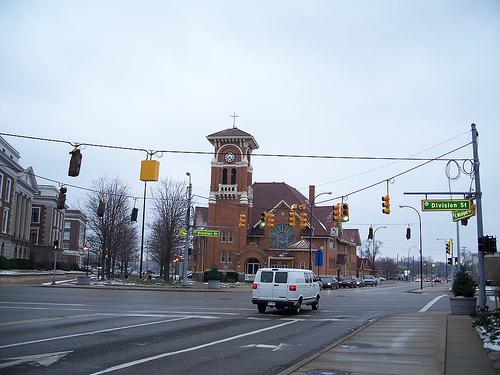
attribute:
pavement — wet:
[123, 309, 180, 359]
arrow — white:
[238, 341, 301, 351]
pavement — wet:
[307, 289, 379, 323]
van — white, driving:
[253, 265, 321, 315]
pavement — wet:
[111, 298, 194, 370]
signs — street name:
[420, 198, 475, 223]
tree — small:
[453, 267, 473, 297]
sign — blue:
[312, 246, 324, 268]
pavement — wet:
[150, 281, 214, 336]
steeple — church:
[202, 109, 264, 206]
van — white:
[247, 263, 327, 317]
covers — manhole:
[303, 337, 370, 374]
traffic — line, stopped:
[319, 277, 338, 289]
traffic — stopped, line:
[336, 275, 358, 288]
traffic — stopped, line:
[347, 277, 363, 287]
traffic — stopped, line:
[361, 276, 377, 287]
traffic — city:
[244, 269, 377, 313]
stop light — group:
[378, 190, 395, 218]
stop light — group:
[328, 197, 353, 224]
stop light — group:
[285, 201, 311, 231]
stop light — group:
[257, 207, 274, 226]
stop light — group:
[235, 205, 247, 230]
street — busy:
[1, 256, 458, 369]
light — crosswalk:
[469, 230, 499, 259]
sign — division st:
[415, 195, 473, 213]